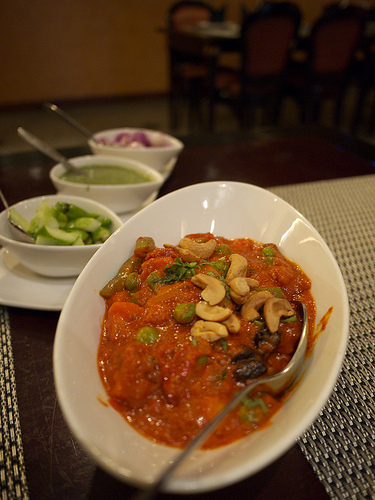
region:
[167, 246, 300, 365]
Nuts on top of red sauce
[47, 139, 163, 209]
a green sauce in dish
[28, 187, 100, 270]
green chunks in a dish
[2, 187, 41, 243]
a spoon in the green chunks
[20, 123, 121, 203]
a spoon in the green sauce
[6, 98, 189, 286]
three small white containers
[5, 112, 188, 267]
three containers with toppings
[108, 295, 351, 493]
a silver spoon in main dish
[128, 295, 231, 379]
green peas in a red sauce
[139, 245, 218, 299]
green leafy stuff on top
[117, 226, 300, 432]
Food in a white bowl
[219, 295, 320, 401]
spoon in a bowl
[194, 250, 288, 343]
cashews in a bow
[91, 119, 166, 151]
onions in a bowl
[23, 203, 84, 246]
green apples in the bowl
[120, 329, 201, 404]
tomato sauce in the bowl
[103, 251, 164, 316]
green vegetables in the bowl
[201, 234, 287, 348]
nuts in the bowl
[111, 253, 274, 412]
Dinner in the bowl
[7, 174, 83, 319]
bowl on a white plate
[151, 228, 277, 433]
a tomato dish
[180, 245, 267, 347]
it appears to be sprinkled with cashews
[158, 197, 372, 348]
the dish is white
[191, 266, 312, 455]
the spoon is silvertone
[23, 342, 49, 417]
the counter appears to be marble or granite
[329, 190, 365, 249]
the mat appears to be woven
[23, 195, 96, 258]
a bowl of zuchini perhaps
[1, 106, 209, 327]
all the bowls are whtie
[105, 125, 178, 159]
this bowl has something purple in it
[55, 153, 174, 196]
this bowl has what looks like guacamole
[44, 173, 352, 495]
A bowl of soup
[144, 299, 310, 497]
Silver spoon in a bowl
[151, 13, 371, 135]
Chairs around a dining table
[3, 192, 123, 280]
Green veggies in a bowl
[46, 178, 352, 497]
The bowl is white and oval shaped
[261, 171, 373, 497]
A silver placemat on the table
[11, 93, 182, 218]
Two bowls with spoons in them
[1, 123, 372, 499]
A brown wooden table surface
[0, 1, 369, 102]
The wall is light brown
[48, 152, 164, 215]
Green soup in a bowl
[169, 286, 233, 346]
The cashews are next to the pea.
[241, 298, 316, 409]
The spoon is inside of the stew.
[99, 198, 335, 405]
The stew is inside a white bowl.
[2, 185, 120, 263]
Green apples are inside the white bowl.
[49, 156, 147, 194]
The green sauce is in the bowl.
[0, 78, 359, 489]
Four bowls are on the table.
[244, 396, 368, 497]
The table has a placemat.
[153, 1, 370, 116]
Table and chairs are seen in the background.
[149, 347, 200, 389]
The sauce is red.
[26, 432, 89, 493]
The table is brown.